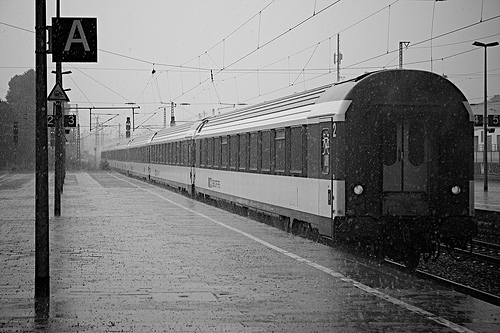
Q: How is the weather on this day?
A: It is overcast.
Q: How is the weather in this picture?
A: It is overcast.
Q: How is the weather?
A: It is overcast.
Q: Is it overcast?
A: Yes, it is overcast.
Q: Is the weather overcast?
A: Yes, it is overcast.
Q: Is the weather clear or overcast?
A: It is overcast.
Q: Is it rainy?
A: No, it is overcast.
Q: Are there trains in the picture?
A: Yes, there is a train.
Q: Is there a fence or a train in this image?
A: Yes, there is a train.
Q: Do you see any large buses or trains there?
A: Yes, there is a large train.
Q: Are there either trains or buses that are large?
A: Yes, the train is large.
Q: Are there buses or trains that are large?
A: Yes, the train is large.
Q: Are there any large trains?
A: Yes, there is a large train.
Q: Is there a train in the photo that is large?
A: Yes, there is a train that is large.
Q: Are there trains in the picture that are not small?
A: Yes, there is a large train.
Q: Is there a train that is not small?
A: Yes, there is a large train.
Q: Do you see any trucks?
A: No, there are no trucks.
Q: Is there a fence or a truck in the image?
A: No, there are no trucks or fences.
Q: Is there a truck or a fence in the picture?
A: No, there are no trucks or fences.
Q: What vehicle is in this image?
A: The vehicle is a train.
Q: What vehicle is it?
A: The vehicle is a train.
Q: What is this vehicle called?
A: This is a train.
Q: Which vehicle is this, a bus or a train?
A: This is a train.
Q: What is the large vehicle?
A: The vehicle is a train.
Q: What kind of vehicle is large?
A: The vehicle is a train.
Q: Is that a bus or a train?
A: That is a train.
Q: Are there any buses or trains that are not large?
A: No, there is a train but it is large.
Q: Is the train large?
A: Yes, the train is large.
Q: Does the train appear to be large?
A: Yes, the train is large.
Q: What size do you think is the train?
A: The train is large.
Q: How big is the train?
A: The train is large.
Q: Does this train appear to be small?
A: No, the train is large.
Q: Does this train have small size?
A: No, the train is large.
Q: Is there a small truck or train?
A: No, there is a train but it is large.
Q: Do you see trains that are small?
A: No, there is a train but it is large.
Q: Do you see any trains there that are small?
A: No, there is a train but it is large.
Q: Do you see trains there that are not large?
A: No, there is a train but it is large.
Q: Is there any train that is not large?
A: No, there is a train but it is large.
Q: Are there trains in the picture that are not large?
A: No, there is a train but it is large.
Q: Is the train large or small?
A: The train is large.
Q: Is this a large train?
A: Yes, this is a large train.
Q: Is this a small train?
A: No, this is a large train.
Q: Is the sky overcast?
A: Yes, the sky is overcast.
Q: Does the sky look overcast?
A: Yes, the sky is overcast.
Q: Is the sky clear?
A: No, the sky is overcast.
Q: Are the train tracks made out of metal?
A: Yes, the train tracks are made of metal.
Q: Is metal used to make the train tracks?
A: Yes, the train tracks are made of metal.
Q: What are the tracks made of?
A: The tracks are made of metal.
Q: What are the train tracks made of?
A: The tracks are made of metal.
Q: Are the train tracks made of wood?
A: No, the train tracks are made of metal.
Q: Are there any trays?
A: No, there are no trays.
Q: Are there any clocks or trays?
A: No, there are no trays or clocks.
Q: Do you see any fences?
A: No, there are no fences.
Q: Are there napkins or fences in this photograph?
A: No, there are no fences or napkins.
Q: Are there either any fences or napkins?
A: No, there are no fences or napkins.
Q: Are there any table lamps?
A: No, there are no table lamps.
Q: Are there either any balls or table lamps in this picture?
A: No, there are no table lamps or balls.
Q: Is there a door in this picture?
A: Yes, there are doors.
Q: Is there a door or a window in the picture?
A: Yes, there are doors.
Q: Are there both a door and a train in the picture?
A: Yes, there are both a door and a train.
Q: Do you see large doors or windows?
A: Yes, there are large doors.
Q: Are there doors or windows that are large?
A: Yes, the doors are large.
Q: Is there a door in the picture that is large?
A: Yes, there are large doors.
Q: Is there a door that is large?
A: Yes, there are doors that are large.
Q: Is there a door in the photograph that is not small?
A: Yes, there are large doors.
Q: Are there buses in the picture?
A: No, there are no buses.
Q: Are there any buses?
A: No, there are no buses.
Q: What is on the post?
A: The sign is on the post.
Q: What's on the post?
A: The sign is on the post.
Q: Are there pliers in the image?
A: No, there are no pliers.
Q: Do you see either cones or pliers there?
A: No, there are no pliers or cones.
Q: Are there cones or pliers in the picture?
A: No, there are no pliers or cones.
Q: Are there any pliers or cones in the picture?
A: No, there are no pliers or cones.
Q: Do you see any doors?
A: Yes, there are doors.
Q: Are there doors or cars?
A: Yes, there are doors.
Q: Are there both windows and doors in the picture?
A: Yes, there are both doors and a window.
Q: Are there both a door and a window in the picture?
A: Yes, there are both a door and a window.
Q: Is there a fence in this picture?
A: No, there are no fences.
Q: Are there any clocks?
A: No, there are no clocks.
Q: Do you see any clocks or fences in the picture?
A: No, there are no clocks or fences.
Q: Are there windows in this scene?
A: Yes, there are windows.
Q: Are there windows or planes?
A: Yes, there are windows.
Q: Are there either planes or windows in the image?
A: Yes, there are windows.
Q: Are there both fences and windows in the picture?
A: No, there are windows but no fences.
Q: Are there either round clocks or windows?
A: Yes, there are round windows.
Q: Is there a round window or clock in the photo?
A: Yes, there are round windows.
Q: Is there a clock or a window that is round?
A: Yes, the windows are round.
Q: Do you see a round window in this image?
A: Yes, there are round windows.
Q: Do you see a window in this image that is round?
A: Yes, there are windows that are round.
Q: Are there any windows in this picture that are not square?
A: Yes, there are round windows.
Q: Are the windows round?
A: Yes, the windows are round.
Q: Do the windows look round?
A: Yes, the windows are round.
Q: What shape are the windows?
A: The windows are round.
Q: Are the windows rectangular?
A: No, the windows are round.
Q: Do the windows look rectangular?
A: No, the windows are round.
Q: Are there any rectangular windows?
A: No, there are windows but they are round.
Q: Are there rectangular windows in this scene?
A: No, there are windows but they are round.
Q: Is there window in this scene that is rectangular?
A: No, there are windows but they are round.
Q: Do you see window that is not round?
A: No, there are windows but they are round.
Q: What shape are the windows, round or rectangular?
A: The windows are round.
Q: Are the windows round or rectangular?
A: The windows are round.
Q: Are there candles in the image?
A: No, there are no candles.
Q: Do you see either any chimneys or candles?
A: No, there are no candles or chimneys.